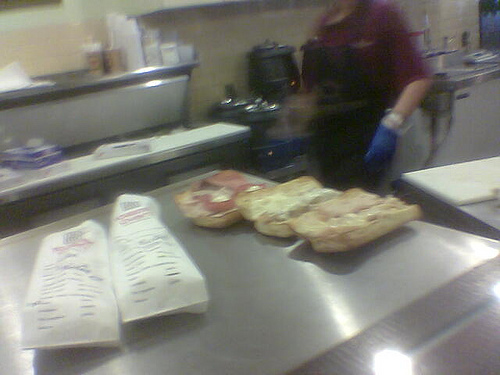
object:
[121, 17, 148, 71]
containers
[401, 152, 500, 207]
cutting board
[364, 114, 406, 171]
glove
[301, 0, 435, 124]
shirt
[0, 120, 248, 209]
area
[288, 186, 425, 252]
bread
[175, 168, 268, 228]
bread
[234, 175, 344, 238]
bread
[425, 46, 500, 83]
sink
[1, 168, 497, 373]
surface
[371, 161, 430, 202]
ground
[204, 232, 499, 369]
steel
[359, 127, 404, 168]
hand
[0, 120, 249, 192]
counter top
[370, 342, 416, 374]
light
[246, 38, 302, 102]
pot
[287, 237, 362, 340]
light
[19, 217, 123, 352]
bag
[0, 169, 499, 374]
counter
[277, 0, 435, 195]
cook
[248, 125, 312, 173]
glove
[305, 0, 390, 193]
apron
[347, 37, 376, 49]
logo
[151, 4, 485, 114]
wall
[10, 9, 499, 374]
kitchen